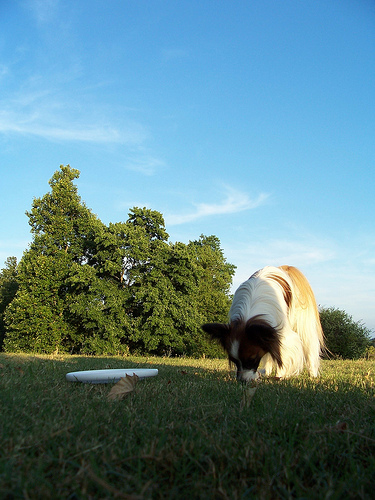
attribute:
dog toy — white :
[66, 364, 158, 387]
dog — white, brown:
[197, 264, 327, 382]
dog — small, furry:
[174, 227, 337, 378]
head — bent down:
[199, 310, 283, 385]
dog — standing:
[197, 250, 338, 386]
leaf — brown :
[104, 369, 141, 409]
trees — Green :
[50, 172, 166, 247]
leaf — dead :
[110, 378, 156, 408]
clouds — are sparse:
[175, 172, 271, 225]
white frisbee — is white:
[72, 355, 166, 397]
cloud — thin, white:
[156, 184, 272, 231]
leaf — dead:
[108, 376, 140, 408]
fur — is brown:
[201, 310, 282, 370]